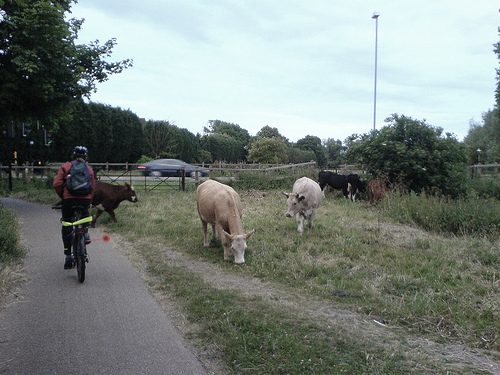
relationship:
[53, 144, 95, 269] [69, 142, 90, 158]
person with helmet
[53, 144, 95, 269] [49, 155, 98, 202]
person wearing jacket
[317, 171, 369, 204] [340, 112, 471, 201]
cow near tree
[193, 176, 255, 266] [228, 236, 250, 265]
cow has white face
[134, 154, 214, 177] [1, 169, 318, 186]
car on road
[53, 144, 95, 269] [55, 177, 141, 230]
person by cow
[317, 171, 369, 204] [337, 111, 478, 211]
cow near tree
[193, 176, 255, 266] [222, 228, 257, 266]
cow has white head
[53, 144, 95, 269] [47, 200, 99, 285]
person rides bike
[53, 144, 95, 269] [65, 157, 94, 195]
person carries backpack